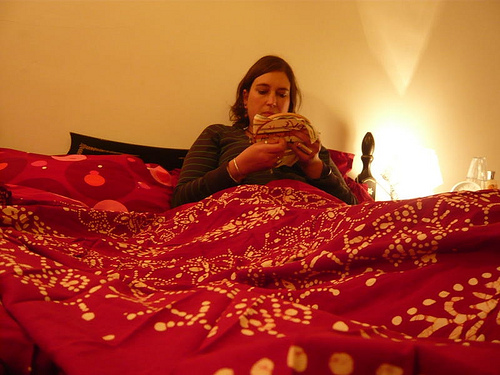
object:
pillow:
[0, 146, 173, 213]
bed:
[0, 131, 499, 374]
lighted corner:
[352, 119, 443, 202]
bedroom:
[0, 0, 499, 374]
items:
[448, 155, 499, 192]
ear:
[241, 88, 249, 105]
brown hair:
[227, 54, 303, 129]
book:
[253, 111, 322, 168]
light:
[373, 127, 445, 203]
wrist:
[229, 152, 251, 175]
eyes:
[255, 88, 270, 96]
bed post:
[355, 132, 377, 202]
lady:
[170, 54, 360, 210]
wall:
[0, 0, 499, 201]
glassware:
[465, 156, 487, 193]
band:
[232, 158, 242, 175]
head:
[227, 54, 301, 126]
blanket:
[0, 179, 499, 373]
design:
[212, 279, 322, 344]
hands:
[236, 136, 290, 174]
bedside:
[361, 141, 499, 201]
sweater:
[169, 123, 360, 208]